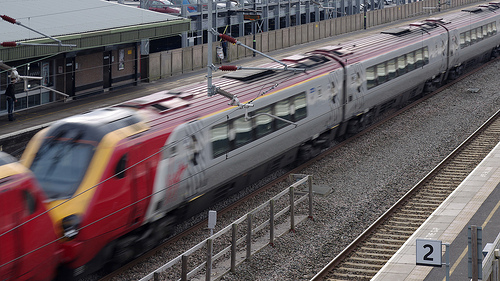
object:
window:
[230, 111, 253, 151]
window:
[256, 103, 275, 140]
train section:
[18, 53, 346, 270]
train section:
[306, 22, 448, 138]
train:
[2, 1, 498, 280]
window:
[28, 139, 95, 197]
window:
[294, 93, 309, 119]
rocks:
[360, 207, 375, 213]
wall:
[76, 45, 138, 92]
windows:
[459, 33, 467, 49]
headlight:
[61, 215, 84, 239]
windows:
[210, 123, 235, 159]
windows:
[364, 65, 380, 87]